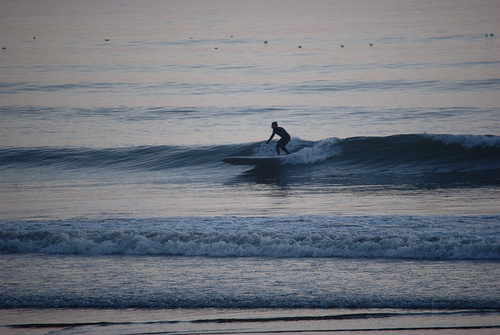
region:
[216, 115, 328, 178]
person surfing on the water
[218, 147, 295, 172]
long and thin surfboard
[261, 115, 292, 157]
person in a black wetsuit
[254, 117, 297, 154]
person crouched down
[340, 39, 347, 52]
something small floating in the water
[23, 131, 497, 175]
long wave with not very much height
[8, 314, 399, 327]
long and skinny wave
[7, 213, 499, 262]
wave rolling into the shore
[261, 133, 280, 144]
arm extended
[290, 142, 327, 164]
water coming off of the board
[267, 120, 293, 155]
surfer on surfboard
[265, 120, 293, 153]
surfer is in shadow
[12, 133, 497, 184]
wave in the ocean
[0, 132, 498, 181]
surfer riding a wave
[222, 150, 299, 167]
surfboard in the ocean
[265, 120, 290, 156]
surfer in the ocean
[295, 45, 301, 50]
buoys bobbing in the ocean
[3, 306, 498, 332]
beach next to ocean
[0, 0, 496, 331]
water is dark and smooth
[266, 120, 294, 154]
surfer is standing up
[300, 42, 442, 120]
The water is calm.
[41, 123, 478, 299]
There are small waves.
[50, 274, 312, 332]
The water is coming to the shore.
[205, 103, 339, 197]
The surfer is riding a wave.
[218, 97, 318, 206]
The person is surfing.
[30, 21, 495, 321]
It is almost night.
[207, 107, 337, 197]
The surfer is in the ocean.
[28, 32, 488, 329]
The person is by the shore.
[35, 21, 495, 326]
The surfer is alone.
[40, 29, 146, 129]
The water is calm.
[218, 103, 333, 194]
They are standing on a surf board.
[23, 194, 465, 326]
The waves are coming in.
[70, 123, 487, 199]
The wave is small.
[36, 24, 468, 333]
He is in the ocean.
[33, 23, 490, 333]
He is surfing alone.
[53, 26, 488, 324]
The water is blue.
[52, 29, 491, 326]
It is getting dark.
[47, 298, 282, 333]
The shore is close.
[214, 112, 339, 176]
A surfer surfing.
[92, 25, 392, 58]
Buoys are in the water.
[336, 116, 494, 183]
The waves are medium.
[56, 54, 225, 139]
The water is blue.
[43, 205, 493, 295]
The waves are making foam.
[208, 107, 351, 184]
The surfer is standing on a surfboard.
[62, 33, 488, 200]
The sun is low in the sky.